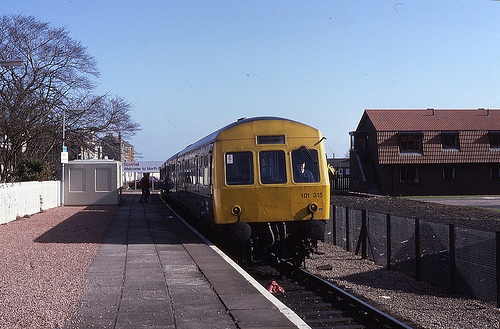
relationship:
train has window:
[158, 116, 330, 272] [225, 153, 253, 184]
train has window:
[158, 116, 330, 272] [259, 151, 286, 186]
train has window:
[158, 116, 330, 272] [292, 149, 320, 183]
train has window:
[158, 116, 330, 272] [257, 135, 286, 145]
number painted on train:
[299, 191, 324, 200] [158, 116, 330, 272]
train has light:
[158, 116, 330, 272] [233, 205, 241, 214]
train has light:
[158, 116, 330, 272] [309, 204, 317, 213]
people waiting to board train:
[140, 170, 153, 202] [158, 116, 330, 272]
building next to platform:
[62, 159, 123, 207] [64, 192, 313, 329]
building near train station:
[348, 109, 499, 197] [1, 157, 499, 328]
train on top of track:
[158, 116, 330, 272] [239, 256, 414, 327]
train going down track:
[158, 116, 330, 272] [239, 256, 414, 327]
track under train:
[239, 256, 414, 327] [158, 116, 330, 272]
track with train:
[239, 256, 414, 327] [158, 116, 330, 272]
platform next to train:
[64, 192, 313, 329] [158, 116, 330, 272]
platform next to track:
[64, 192, 313, 329] [239, 256, 414, 327]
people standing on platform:
[140, 170, 153, 202] [64, 192, 313, 329]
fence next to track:
[324, 202, 500, 306] [239, 256, 414, 327]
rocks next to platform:
[1, 205, 117, 328] [64, 192, 313, 329]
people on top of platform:
[140, 170, 153, 202] [64, 192, 313, 329]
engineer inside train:
[296, 161, 316, 181] [158, 116, 330, 272]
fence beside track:
[324, 202, 500, 306] [239, 256, 414, 327]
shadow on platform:
[35, 179, 214, 245] [64, 192, 313, 329]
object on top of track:
[267, 279, 284, 296] [239, 256, 414, 327]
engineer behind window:
[296, 161, 316, 181] [292, 149, 320, 183]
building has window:
[348, 109, 499, 197] [399, 167, 419, 181]